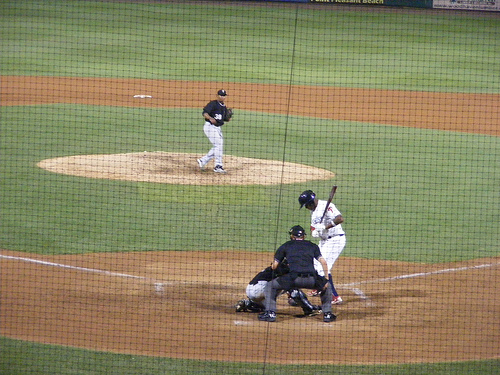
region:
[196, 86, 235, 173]
a baseball pitcher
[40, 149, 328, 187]
a brown pitcher's mound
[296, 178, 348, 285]
a baseball player at bat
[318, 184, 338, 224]
a black baseball bat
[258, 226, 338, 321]
a umpire wearing black protection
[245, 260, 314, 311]
a baseball catcher on ground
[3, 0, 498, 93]
a patch of green astroturf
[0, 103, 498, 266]
a patch of green astroturf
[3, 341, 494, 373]
a patch of green astroturf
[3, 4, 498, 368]
black protective stadium netting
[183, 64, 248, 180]
the pitcher is on the mound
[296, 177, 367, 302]
the batter decided not to swing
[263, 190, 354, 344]
the umpire is making the call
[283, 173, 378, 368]
the batter has a white uniform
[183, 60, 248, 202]
the pitcher is dressed in white & black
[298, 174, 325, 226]
the batters helmet is black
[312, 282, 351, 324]
the batter's shoes are red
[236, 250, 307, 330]
the catcher is in the dirt after the ball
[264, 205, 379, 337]
the umpire has a black shirt on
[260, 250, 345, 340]
the umpire is wearing grey pants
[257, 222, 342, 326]
the referee who is at home plate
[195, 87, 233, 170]
the pitcher on the mound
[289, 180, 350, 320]
the batter with the bat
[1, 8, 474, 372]
the fence by the stands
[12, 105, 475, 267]
the center of the baseball field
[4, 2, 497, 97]
the outfield of the field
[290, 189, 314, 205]
the helmet of the man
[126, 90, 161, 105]
the second base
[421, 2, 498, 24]
a sign on the fence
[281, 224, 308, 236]
the referee hat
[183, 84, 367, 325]
Four baseball players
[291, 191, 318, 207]
Helmet is black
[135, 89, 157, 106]
Second base behind pitcher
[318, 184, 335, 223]
Baseball bat is brown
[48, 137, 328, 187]
Pitching mound is brown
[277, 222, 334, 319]
Umpire calls the play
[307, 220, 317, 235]
Red stripe on uniform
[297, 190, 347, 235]
Player looking down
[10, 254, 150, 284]
White line by home plate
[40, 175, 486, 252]
Grass between home plate and pitcher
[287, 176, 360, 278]
Man wearing a blue helmet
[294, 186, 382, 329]
The man is standing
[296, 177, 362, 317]
The man has a white uniform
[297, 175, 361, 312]
Man is holding a bat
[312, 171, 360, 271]
The bat is black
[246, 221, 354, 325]
Man is crouching down on the base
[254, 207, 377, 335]
Man is wearing a black uniform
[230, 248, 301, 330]
Player is sliding into the base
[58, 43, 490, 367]
Dirt and grass field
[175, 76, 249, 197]
Pitcher is standing on a dirt mound